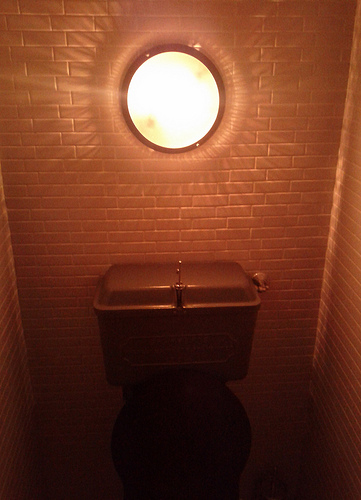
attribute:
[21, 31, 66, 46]
brick — white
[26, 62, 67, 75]
brick — white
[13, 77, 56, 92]
brick — white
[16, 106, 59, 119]
brick — white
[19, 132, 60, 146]
brick — white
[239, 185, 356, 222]
wall — white, bricks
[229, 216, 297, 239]
bricks — white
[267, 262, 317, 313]
bricks — white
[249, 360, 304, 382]
bricks — white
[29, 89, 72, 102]
brick — white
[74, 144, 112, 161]
brick — white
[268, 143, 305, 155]
brick — white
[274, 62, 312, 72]
brick — white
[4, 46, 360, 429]
wall — white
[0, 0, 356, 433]
wall — white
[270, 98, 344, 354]
wall — white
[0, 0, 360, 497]
bricks — white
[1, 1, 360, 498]
wall — white